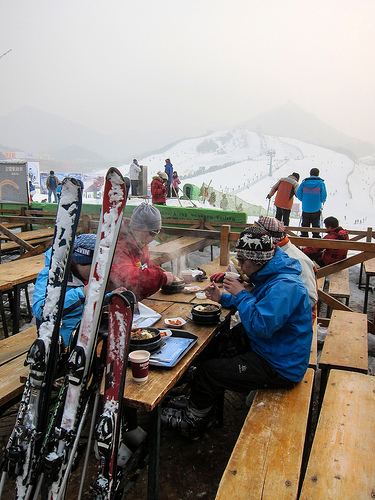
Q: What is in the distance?
A: Ski drop.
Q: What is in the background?
A: Hills.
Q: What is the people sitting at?
A: Benches.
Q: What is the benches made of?
A: Wood.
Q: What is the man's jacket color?
A: Blue.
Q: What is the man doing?
A: Drinking.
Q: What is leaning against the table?
A: Skis.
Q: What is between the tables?
A: Wood fence.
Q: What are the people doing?
A: Eating.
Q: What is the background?
A: Snow mountains.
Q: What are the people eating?
A: Hot food.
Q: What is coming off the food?
A: Steam.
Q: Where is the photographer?
A: At a ski resort.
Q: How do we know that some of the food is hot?
A: Steam.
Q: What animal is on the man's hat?
A: A moose.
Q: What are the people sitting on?
A: Benches.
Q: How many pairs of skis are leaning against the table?
A: Three.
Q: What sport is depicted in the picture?
A: Skiing.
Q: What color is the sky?
A: White.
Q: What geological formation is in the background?
A: Mountains.